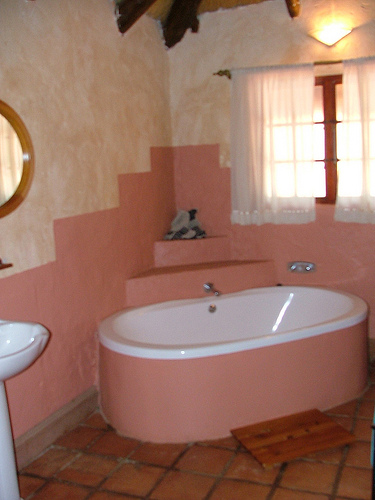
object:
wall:
[168, 0, 373, 359]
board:
[229, 406, 360, 471]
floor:
[14, 362, 374, 498]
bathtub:
[97, 283, 368, 445]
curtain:
[229, 55, 316, 227]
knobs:
[288, 260, 315, 275]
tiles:
[100, 459, 168, 498]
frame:
[312, 72, 343, 206]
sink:
[0, 321, 50, 500]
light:
[293, 122, 325, 162]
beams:
[114, 2, 154, 34]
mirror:
[0, 113, 25, 207]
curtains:
[231, 55, 375, 229]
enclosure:
[2, 145, 372, 438]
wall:
[3, 0, 167, 446]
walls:
[2, 0, 374, 466]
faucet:
[202, 281, 221, 299]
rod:
[215, 55, 373, 80]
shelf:
[124, 232, 279, 309]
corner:
[158, 6, 185, 237]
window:
[235, 71, 373, 209]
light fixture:
[298, 17, 360, 48]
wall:
[164, 6, 238, 144]